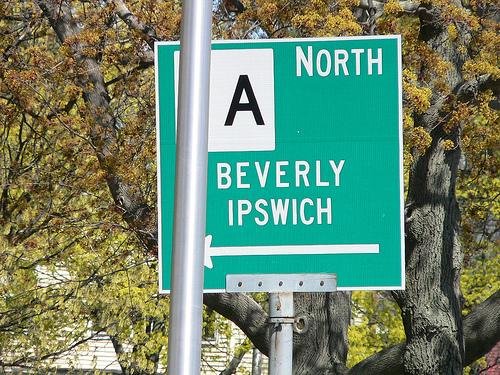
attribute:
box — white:
[171, 50, 279, 152]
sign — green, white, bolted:
[151, 35, 408, 292]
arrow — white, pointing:
[204, 233, 380, 269]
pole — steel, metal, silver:
[164, 1, 213, 375]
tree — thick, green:
[1, 1, 499, 374]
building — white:
[3, 234, 270, 375]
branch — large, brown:
[37, 3, 273, 355]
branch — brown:
[104, 0, 163, 50]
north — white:
[296, 44, 386, 77]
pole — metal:
[266, 291, 297, 374]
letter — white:
[216, 162, 232, 191]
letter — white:
[235, 162, 252, 190]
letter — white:
[254, 162, 272, 189]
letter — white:
[276, 160, 291, 190]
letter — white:
[294, 160, 311, 188]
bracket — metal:
[227, 273, 339, 293]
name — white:
[216, 161, 346, 188]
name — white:
[226, 196, 334, 226]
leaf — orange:
[66, 31, 85, 45]